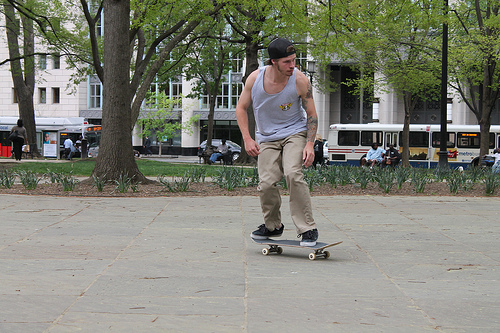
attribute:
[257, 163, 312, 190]
knees — bent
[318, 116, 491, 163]
man's shirt — green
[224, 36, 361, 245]
man — white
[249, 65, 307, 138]
muscle shirt — man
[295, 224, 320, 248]
shoe — white, black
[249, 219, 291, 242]
shoe — white, black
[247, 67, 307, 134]
muscle shirt — man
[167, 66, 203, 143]
column — large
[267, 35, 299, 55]
cap — ball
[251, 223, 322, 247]
shoes — black